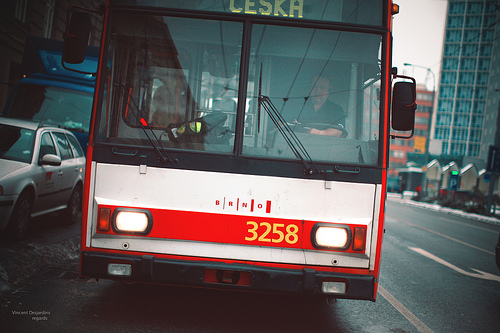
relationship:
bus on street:
[75, 0, 413, 304] [1, 194, 497, 332]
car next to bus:
[1, 113, 88, 242] [75, 0, 413, 304]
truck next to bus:
[3, 30, 114, 202] [75, 0, 413, 304]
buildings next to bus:
[424, 0, 500, 180] [75, 0, 413, 304]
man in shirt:
[285, 64, 354, 143] [287, 99, 354, 142]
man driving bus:
[285, 64, 354, 143] [75, 0, 413, 304]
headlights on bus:
[309, 224, 353, 255] [75, 0, 413, 304]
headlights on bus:
[108, 207, 152, 237] [75, 0, 413, 304]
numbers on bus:
[243, 220, 302, 247] [75, 0, 413, 304]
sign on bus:
[224, 0, 307, 21] [75, 0, 413, 304]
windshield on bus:
[91, 2, 385, 170] [75, 0, 413, 304]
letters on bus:
[213, 197, 266, 211] [75, 0, 413, 304]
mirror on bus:
[60, 6, 95, 65] [75, 0, 413, 304]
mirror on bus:
[389, 80, 420, 134] [75, 0, 413, 304]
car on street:
[1, 113, 88, 242] [1, 194, 497, 332]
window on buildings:
[457, 86, 471, 101] [424, 0, 500, 180]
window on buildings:
[463, 41, 480, 59] [424, 0, 500, 180]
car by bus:
[1, 113, 88, 242] [75, 0, 413, 304]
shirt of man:
[287, 99, 354, 142] [285, 64, 354, 143]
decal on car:
[41, 170, 54, 184] [1, 113, 88, 242]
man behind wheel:
[285, 64, 354, 143] [290, 119, 349, 140]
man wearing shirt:
[285, 64, 354, 143] [287, 99, 354, 142]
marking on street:
[407, 240, 500, 287] [1, 194, 497, 332]